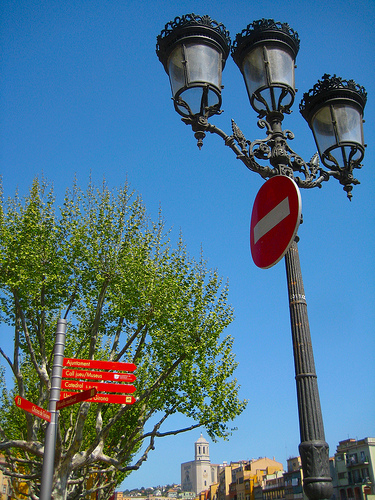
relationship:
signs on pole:
[13, 345, 140, 427] [37, 312, 64, 500]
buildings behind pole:
[107, 449, 374, 497] [37, 312, 64, 500]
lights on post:
[149, 10, 367, 201] [254, 147, 351, 499]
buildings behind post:
[107, 449, 374, 497] [254, 147, 351, 499]